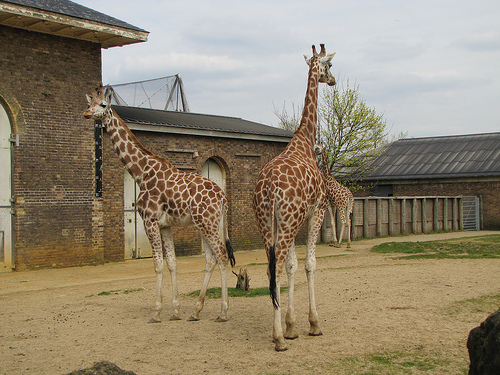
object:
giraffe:
[57, 69, 246, 334]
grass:
[372, 211, 467, 273]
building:
[110, 84, 297, 248]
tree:
[329, 90, 379, 146]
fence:
[131, 65, 191, 116]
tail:
[203, 223, 246, 286]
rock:
[454, 298, 496, 356]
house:
[102, 105, 290, 261]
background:
[46, 42, 442, 311]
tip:
[229, 254, 254, 272]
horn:
[80, 84, 111, 105]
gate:
[434, 188, 484, 267]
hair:
[266, 255, 274, 290]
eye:
[97, 100, 110, 115]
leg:
[123, 225, 188, 347]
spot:
[161, 184, 200, 220]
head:
[73, 73, 127, 135]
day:
[201, 6, 271, 79]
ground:
[26, 274, 103, 323]